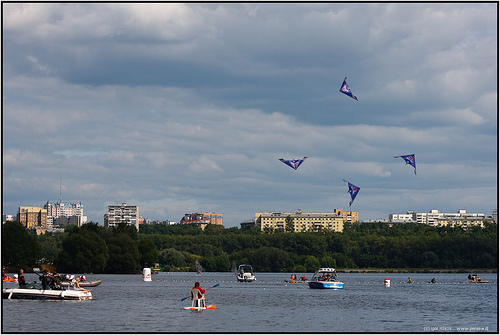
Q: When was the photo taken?
A: Daytime.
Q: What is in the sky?
A: Clouds.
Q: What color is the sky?
A: Blue.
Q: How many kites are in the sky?
A: Four.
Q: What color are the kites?
A: White and blue.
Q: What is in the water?
A: Boats.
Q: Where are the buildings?
A: Background.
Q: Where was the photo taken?
A: In a bay.